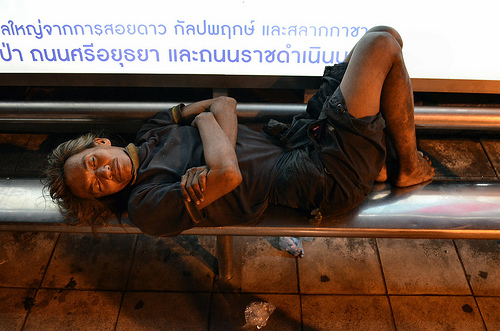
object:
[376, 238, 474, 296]
tile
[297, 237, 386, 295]
tile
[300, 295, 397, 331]
tile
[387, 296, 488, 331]
tile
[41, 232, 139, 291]
tile